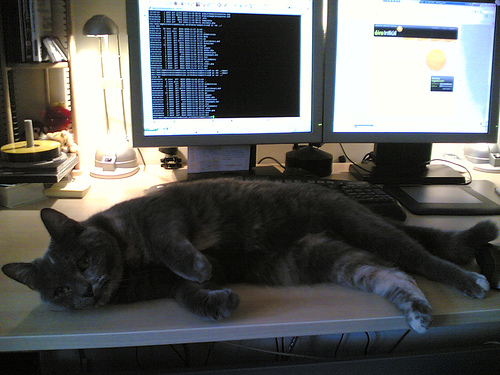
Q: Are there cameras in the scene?
A: No, there are no cameras.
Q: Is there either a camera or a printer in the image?
A: No, there are no cameras or printers.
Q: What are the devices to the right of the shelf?
A: The devices are monitors.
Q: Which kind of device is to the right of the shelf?
A: The devices are monitors.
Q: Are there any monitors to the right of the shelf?
A: Yes, there are monitors to the right of the shelf.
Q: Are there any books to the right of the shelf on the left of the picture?
A: No, there are monitors to the right of the shelf.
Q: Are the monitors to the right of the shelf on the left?
A: Yes, the monitors are to the right of the shelf.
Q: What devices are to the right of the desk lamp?
A: The devices are monitors.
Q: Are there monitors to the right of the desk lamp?
A: Yes, there are monitors to the right of the desk lamp.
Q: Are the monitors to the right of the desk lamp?
A: Yes, the monitors are to the right of the desk lamp.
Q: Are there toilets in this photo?
A: No, there are no toilets.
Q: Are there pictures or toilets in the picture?
A: No, there are no toilets or pictures.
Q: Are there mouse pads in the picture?
A: Yes, there is a mouse pad.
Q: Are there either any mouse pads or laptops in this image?
A: Yes, there is a mouse pad.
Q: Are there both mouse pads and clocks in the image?
A: No, there is a mouse pad but no clocks.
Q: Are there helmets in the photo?
A: No, there are no helmets.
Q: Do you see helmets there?
A: No, there are no helmets.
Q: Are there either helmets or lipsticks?
A: No, there are no helmets or lipsticks.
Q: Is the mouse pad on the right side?
A: Yes, the mouse pad is on the right of the image.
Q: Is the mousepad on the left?
A: No, the mousepad is on the right of the image.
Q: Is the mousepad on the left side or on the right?
A: The mousepad is on the right of the image.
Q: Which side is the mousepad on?
A: The mousepad is on the right of the image.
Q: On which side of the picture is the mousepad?
A: The mousepad is on the right of the image.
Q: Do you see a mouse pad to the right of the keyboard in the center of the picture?
A: Yes, there is a mouse pad to the right of the keyboard.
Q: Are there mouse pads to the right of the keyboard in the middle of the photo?
A: Yes, there is a mouse pad to the right of the keyboard.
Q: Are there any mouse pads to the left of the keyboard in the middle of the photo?
A: No, the mouse pad is to the right of the keyboard.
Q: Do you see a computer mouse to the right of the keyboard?
A: No, there is a mouse pad to the right of the keyboard.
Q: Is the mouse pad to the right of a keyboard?
A: Yes, the mouse pad is to the right of a keyboard.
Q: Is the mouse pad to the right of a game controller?
A: No, the mouse pad is to the right of a keyboard.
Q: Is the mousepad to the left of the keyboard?
A: No, the mousepad is to the right of the keyboard.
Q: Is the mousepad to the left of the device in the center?
A: No, the mousepad is to the right of the keyboard.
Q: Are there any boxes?
A: No, there are no boxes.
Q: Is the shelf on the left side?
A: Yes, the shelf is on the left of the image.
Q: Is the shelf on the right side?
A: No, the shelf is on the left of the image.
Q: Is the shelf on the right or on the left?
A: The shelf is on the left of the image.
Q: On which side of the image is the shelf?
A: The shelf is on the left of the image.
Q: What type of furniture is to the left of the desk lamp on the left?
A: The piece of furniture is a shelf.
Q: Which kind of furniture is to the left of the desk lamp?
A: The piece of furniture is a shelf.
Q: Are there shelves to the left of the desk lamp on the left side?
A: Yes, there is a shelf to the left of the desk lamp.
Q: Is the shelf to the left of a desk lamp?
A: Yes, the shelf is to the left of a desk lamp.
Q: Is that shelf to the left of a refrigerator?
A: No, the shelf is to the left of a desk lamp.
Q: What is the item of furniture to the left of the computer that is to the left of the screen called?
A: The piece of furniture is a shelf.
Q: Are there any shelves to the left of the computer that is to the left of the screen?
A: Yes, there is a shelf to the left of the computer.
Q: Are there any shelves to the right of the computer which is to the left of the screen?
A: No, the shelf is to the left of the computer.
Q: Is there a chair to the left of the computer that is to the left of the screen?
A: No, there is a shelf to the left of the computer.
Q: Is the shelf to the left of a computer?
A: Yes, the shelf is to the left of a computer.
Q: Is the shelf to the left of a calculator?
A: No, the shelf is to the left of a computer.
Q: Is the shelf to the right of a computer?
A: No, the shelf is to the left of a computer.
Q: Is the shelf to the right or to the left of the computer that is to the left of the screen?
A: The shelf is to the left of the computer.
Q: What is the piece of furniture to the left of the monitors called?
A: The piece of furniture is a shelf.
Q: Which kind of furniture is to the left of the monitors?
A: The piece of furniture is a shelf.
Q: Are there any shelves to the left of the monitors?
A: Yes, there is a shelf to the left of the monitors.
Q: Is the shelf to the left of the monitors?
A: Yes, the shelf is to the left of the monitors.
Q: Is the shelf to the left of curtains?
A: No, the shelf is to the left of the monitors.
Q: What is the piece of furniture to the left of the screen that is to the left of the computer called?
A: The piece of furniture is a shelf.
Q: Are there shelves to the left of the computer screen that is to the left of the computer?
A: Yes, there is a shelf to the left of the screen.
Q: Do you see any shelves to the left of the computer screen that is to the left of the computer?
A: Yes, there is a shelf to the left of the screen.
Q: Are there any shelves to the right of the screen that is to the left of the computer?
A: No, the shelf is to the left of the screen.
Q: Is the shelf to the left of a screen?
A: Yes, the shelf is to the left of a screen.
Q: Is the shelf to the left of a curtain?
A: No, the shelf is to the left of a screen.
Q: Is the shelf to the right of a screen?
A: No, the shelf is to the left of a screen.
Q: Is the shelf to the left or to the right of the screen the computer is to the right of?
A: The shelf is to the left of the screen.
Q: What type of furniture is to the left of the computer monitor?
A: The piece of furniture is a shelf.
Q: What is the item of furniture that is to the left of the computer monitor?
A: The piece of furniture is a shelf.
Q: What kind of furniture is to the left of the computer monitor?
A: The piece of furniture is a shelf.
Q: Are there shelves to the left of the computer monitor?
A: Yes, there is a shelf to the left of the computer monitor.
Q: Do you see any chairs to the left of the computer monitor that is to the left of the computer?
A: No, there is a shelf to the left of the computer monitor.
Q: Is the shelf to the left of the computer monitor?
A: Yes, the shelf is to the left of the computer monitor.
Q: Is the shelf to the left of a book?
A: No, the shelf is to the left of the computer monitor.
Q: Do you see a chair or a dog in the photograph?
A: No, there are no chairs or dogs.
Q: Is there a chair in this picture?
A: No, there are no chairs.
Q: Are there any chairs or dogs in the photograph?
A: No, there are no chairs or dogs.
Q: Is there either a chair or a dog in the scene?
A: No, there are no chairs or dogs.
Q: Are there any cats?
A: Yes, there is a cat.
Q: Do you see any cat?
A: Yes, there is a cat.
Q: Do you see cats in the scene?
A: Yes, there is a cat.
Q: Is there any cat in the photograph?
A: Yes, there is a cat.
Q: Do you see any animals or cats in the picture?
A: Yes, there is a cat.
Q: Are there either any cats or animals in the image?
A: Yes, there is a cat.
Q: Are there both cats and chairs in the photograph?
A: No, there is a cat but no chairs.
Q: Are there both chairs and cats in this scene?
A: No, there is a cat but no chairs.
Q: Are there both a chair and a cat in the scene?
A: No, there is a cat but no chairs.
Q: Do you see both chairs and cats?
A: No, there is a cat but no chairs.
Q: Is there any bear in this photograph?
A: No, there are no bears.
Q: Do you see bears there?
A: No, there are no bears.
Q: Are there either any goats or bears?
A: No, there are no bears or goats.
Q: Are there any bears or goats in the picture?
A: No, there are no bears or goats.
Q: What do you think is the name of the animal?
A: The animal is a cat.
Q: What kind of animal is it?
A: The animal is a cat.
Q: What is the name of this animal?
A: This is a cat.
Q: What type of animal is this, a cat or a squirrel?
A: This is a cat.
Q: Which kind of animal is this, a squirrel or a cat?
A: This is a cat.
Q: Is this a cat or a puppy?
A: This is a cat.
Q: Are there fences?
A: No, there are no fences.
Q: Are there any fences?
A: No, there are no fences.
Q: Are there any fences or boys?
A: No, there are no fences or boys.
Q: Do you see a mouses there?
A: No, there are no computer mousess.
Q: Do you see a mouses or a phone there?
A: No, there are no computer mousess or phones.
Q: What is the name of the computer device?
A: The device is a screen.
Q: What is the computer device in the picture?
A: The device is a screen.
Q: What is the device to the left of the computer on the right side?
A: The device is a screen.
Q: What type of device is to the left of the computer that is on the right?
A: The device is a screen.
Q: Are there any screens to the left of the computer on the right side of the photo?
A: Yes, there is a screen to the left of the computer.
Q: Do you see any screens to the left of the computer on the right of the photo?
A: Yes, there is a screen to the left of the computer.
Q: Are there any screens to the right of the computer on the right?
A: No, the screen is to the left of the computer.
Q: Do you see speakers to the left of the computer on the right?
A: No, there is a screen to the left of the computer.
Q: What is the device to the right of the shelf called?
A: The device is a screen.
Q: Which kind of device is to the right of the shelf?
A: The device is a screen.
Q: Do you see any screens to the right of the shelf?
A: Yes, there is a screen to the right of the shelf.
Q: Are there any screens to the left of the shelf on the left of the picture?
A: No, the screen is to the right of the shelf.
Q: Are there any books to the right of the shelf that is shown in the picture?
A: No, there is a screen to the right of the shelf.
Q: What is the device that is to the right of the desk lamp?
A: The device is a screen.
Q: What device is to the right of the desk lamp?
A: The device is a screen.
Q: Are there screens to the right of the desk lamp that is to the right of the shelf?
A: Yes, there is a screen to the right of the desk lamp.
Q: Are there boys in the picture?
A: No, there are no boys.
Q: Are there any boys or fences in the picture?
A: No, there are no boys or fences.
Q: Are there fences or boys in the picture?
A: No, there are no boys or fences.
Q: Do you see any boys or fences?
A: No, there are no boys or fences.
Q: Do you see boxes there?
A: No, there are no boxes.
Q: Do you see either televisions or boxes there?
A: No, there are no boxes or televisions.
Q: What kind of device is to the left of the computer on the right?
A: The device is a computer monitor.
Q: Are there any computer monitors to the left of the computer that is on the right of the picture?
A: Yes, there is a computer monitor to the left of the computer.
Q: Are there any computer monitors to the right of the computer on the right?
A: No, the computer monitor is to the left of the computer.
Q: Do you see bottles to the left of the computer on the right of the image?
A: No, there is a computer monitor to the left of the computer.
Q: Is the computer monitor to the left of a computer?
A: Yes, the computer monitor is to the left of a computer.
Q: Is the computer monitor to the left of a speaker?
A: No, the computer monitor is to the left of a computer.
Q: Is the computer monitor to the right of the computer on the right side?
A: No, the computer monitor is to the left of the computer.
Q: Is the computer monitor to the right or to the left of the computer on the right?
A: The computer monitor is to the left of the computer.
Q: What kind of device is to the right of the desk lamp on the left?
A: The device is a computer monitor.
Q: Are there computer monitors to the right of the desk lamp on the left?
A: Yes, there is a computer monitor to the right of the desk lamp.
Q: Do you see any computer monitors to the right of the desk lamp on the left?
A: Yes, there is a computer monitor to the right of the desk lamp.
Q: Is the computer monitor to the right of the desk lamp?
A: Yes, the computer monitor is to the right of the desk lamp.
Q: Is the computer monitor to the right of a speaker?
A: No, the computer monitor is to the right of the desk lamp.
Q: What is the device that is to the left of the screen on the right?
A: The device is a computer monitor.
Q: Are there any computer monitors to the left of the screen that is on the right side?
A: Yes, there is a computer monitor to the left of the screen.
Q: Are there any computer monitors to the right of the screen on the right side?
A: No, the computer monitor is to the left of the screen.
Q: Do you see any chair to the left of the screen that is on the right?
A: No, there is a computer monitor to the left of the screen.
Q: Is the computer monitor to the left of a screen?
A: Yes, the computer monitor is to the left of a screen.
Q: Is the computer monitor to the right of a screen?
A: No, the computer monitor is to the left of a screen.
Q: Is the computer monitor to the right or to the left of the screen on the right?
A: The computer monitor is to the left of the screen.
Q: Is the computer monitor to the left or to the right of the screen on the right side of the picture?
A: The computer monitor is to the left of the screen.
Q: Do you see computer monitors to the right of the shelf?
A: Yes, there is a computer monitor to the right of the shelf.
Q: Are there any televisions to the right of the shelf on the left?
A: No, there is a computer monitor to the right of the shelf.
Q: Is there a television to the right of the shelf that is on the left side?
A: No, there is a computer monitor to the right of the shelf.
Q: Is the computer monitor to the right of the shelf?
A: Yes, the computer monitor is to the right of the shelf.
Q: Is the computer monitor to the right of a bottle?
A: No, the computer monitor is to the right of the shelf.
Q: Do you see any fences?
A: No, there are no fences.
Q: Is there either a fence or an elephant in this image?
A: No, there are no fences or elephants.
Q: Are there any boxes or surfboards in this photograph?
A: No, there are no boxes or surfboards.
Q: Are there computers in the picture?
A: Yes, there is a computer.